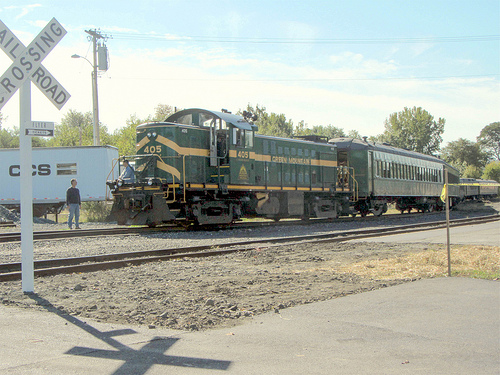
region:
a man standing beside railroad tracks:
[63, 176, 83, 228]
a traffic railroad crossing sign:
[0, 12, 71, 110]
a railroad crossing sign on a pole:
[1, 16, 71, 294]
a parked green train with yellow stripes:
[102, 106, 497, 229]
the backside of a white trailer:
[1, 145, 118, 207]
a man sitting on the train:
[107, 158, 159, 193]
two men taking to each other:
[63, 158, 135, 227]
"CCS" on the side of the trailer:
[6, 163, 53, 178]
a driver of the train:
[115, 158, 137, 188]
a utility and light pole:
[71, 25, 114, 143]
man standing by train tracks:
[59, 170, 87, 225]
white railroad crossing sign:
[2, 18, 64, 307]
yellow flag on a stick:
[432, 162, 459, 276]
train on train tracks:
[125, 103, 475, 213]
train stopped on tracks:
[130, 96, 486, 232]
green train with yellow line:
[125, 99, 496, 215]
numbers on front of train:
[130, 132, 180, 163]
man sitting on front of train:
[111, 156, 134, 188]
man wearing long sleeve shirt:
[55, 178, 87, 228]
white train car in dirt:
[5, 146, 110, 198]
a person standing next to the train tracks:
[63, 178, 94, 242]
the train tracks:
[37, 229, 331, 282]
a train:
[116, 104, 473, 230]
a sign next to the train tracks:
[437, 168, 457, 278]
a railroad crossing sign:
[3, 20, 85, 295]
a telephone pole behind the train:
[77, 31, 113, 143]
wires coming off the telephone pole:
[111, 35, 481, 78]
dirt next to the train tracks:
[78, 255, 253, 325]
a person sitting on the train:
[112, 159, 137, 174]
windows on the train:
[371, 154, 453, 180]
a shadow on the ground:
[89, 327, 163, 370]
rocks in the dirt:
[167, 293, 239, 324]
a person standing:
[63, 177, 87, 230]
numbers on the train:
[144, 145, 164, 155]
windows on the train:
[373, 159, 425, 181]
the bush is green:
[383, 110, 438, 140]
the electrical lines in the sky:
[183, 34, 232, 54]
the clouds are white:
[129, 50, 181, 75]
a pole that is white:
[23, 202, 43, 294]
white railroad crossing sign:
[11, 20, 65, 100]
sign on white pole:
[0, 25, 87, 310]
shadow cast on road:
[6, 278, 193, 370]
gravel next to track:
[120, 257, 289, 324]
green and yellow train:
[122, 103, 440, 217]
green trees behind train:
[197, 95, 481, 198]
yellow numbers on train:
[140, 134, 168, 164]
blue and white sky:
[144, 2, 333, 93]